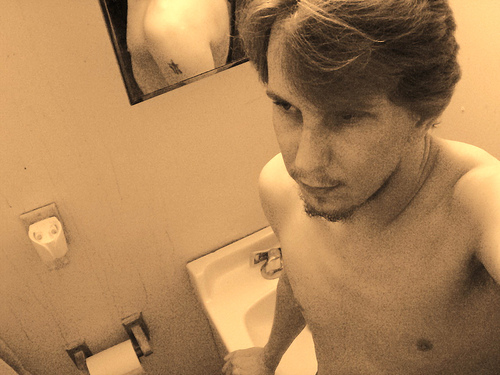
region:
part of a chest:
[343, 269, 370, 313]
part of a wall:
[138, 182, 188, 254]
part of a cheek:
[350, 145, 375, 208]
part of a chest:
[383, 300, 408, 357]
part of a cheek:
[345, 175, 367, 252]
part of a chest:
[361, 220, 397, 265]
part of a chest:
[325, 285, 368, 365]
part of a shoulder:
[459, 180, 484, 232]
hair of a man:
[343, 24, 390, 81]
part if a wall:
[113, 235, 151, 287]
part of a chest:
[344, 277, 386, 344]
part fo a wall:
[158, 263, 213, 336]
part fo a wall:
[128, 210, 165, 274]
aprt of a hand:
[273, 304, 291, 330]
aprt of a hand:
[268, 310, 288, 347]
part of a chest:
[341, 242, 393, 332]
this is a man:
[258, 24, 404, 372]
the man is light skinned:
[332, 227, 404, 313]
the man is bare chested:
[279, 241, 424, 373]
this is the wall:
[133, 129, 225, 243]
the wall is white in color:
[124, 135, 211, 197]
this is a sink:
[198, 277, 259, 328]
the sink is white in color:
[215, 251, 241, 292]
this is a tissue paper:
[91, 348, 144, 373]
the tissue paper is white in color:
[110, 345, 133, 360]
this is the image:
[116, 23, 198, 65]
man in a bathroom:
[211, 12, 478, 362]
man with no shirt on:
[133, 18, 485, 374]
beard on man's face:
[278, 165, 361, 229]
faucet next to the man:
[248, 244, 284, 284]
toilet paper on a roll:
[73, 320, 155, 374]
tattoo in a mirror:
[156, 49, 196, 86]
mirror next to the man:
[83, 9, 223, 134]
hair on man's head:
[252, 10, 446, 98]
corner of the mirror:
[109, 72, 162, 124]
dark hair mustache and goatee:
[283, 166, 361, 225]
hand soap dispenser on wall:
[14, 199, 78, 281]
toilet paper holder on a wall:
[61, 303, 158, 374]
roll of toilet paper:
[57, 308, 151, 373]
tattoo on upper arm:
[129, 6, 200, 84]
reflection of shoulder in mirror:
[92, 2, 237, 119]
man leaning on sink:
[201, 3, 402, 373]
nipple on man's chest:
[396, 321, 441, 365]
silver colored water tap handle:
[250, 243, 286, 280]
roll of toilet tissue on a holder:
[65, 307, 155, 374]